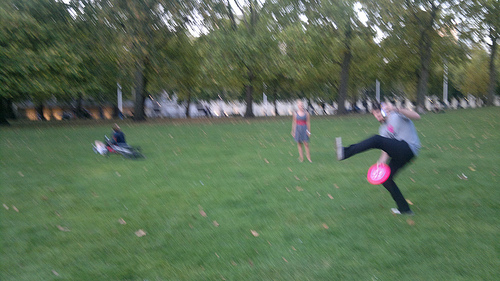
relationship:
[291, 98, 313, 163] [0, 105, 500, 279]
person on grass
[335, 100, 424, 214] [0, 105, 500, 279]
man on grass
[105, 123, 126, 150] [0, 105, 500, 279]
person on grass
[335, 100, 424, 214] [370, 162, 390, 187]
man holds frisbee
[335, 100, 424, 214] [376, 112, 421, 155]
man wears shirt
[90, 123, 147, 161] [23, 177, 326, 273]
person in grass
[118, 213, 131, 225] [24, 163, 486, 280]
leaf in grass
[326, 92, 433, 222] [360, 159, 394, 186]
man playing frisbee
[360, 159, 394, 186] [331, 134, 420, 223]
frisbee between legs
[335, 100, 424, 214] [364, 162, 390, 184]
man playing with frisbee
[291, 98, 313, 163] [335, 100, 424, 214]
person watching man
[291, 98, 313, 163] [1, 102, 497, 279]
person standing on field